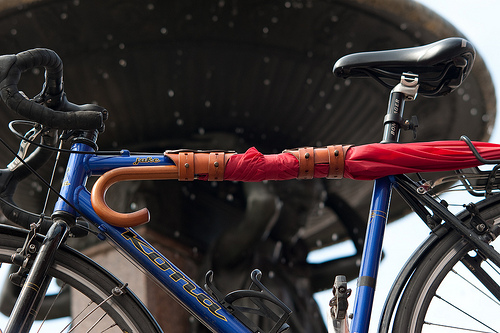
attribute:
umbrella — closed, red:
[84, 135, 499, 233]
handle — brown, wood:
[88, 161, 177, 234]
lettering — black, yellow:
[122, 227, 233, 325]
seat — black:
[326, 34, 482, 105]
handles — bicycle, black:
[2, 44, 114, 135]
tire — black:
[2, 219, 166, 332]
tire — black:
[370, 190, 499, 333]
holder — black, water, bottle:
[203, 264, 302, 332]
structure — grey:
[5, 3, 498, 121]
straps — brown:
[177, 141, 346, 187]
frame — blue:
[60, 135, 403, 332]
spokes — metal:
[41, 295, 105, 332]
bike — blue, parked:
[1, 31, 493, 331]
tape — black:
[19, 104, 65, 126]